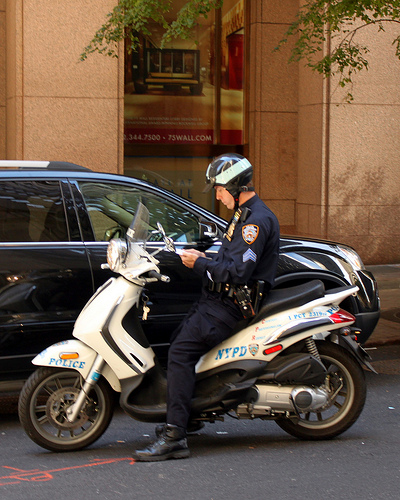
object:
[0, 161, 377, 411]
car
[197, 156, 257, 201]
safety helmet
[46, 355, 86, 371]
word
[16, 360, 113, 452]
front tire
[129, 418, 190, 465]
black boot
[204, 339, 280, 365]
sticker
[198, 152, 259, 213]
helmet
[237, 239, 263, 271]
stripes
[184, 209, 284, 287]
sleeve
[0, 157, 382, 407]
suv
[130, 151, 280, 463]
police officer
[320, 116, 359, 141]
ground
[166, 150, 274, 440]
policeman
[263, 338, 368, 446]
wheel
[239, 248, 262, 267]
patch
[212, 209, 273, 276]
uniform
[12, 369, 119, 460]
wheel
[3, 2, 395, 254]
building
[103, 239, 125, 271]
headlight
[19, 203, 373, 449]
motorcycle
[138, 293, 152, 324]
keys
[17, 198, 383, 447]
bike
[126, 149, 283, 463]
officer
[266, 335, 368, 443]
tire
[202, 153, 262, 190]
helmet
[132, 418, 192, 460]
foot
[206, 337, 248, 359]
letters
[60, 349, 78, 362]
headlight